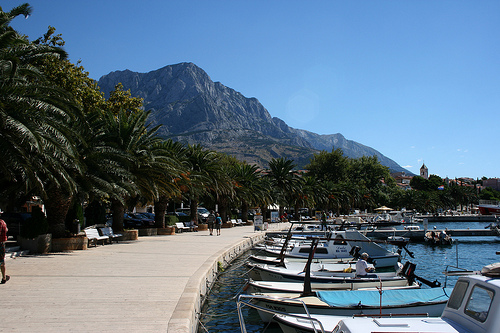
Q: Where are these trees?
A: Along the walkway.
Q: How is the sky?
A: Clear.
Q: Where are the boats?
A: On the water.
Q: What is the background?
A: A mountain.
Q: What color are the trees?
A: Green.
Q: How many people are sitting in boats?
A: One.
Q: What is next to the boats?
A: A walkway.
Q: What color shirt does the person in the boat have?
A: White.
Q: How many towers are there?
A: One.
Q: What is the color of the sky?
A: Blue.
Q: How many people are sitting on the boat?
A: One.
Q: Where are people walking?
A: In front of palm trees.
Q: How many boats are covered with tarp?
A: One.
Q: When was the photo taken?
A: Sunny day.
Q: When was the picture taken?
A: Daytime.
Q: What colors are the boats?
A: White.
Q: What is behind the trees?
A: A mountain.